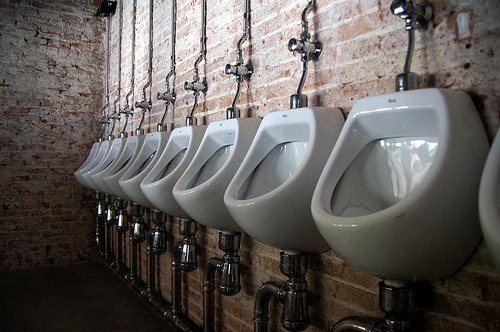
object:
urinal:
[222, 107, 343, 253]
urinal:
[311, 86, 491, 282]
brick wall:
[102, 0, 494, 332]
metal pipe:
[287, 0, 324, 109]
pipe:
[253, 251, 309, 332]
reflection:
[380, 138, 439, 199]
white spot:
[455, 13, 472, 39]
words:
[283, 114, 288, 117]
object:
[93, 0, 118, 19]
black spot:
[463, 62, 470, 69]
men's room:
[0, 0, 495, 331]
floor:
[0, 271, 184, 331]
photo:
[2, 0, 499, 332]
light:
[97, 0, 428, 142]